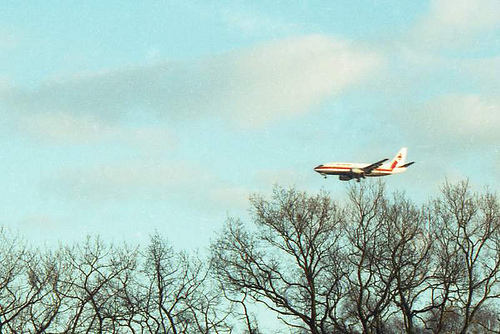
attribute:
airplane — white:
[308, 144, 417, 183]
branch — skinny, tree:
[223, 282, 255, 332]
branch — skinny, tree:
[189, 291, 214, 331]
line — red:
[307, 156, 376, 185]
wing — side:
[398, 158, 422, 173]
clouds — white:
[207, 46, 376, 121]